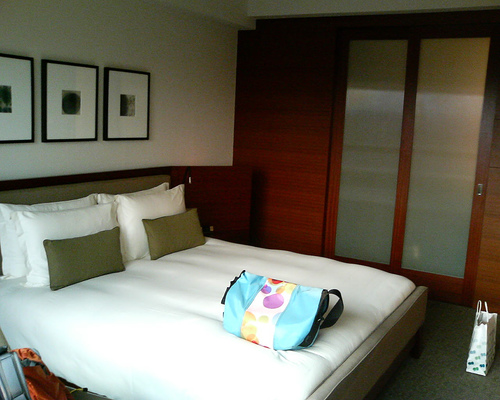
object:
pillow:
[42, 226, 124, 291]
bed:
[0, 172, 428, 400]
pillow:
[0, 193, 98, 278]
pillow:
[97, 181, 169, 205]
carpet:
[404, 307, 496, 399]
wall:
[1, 0, 238, 180]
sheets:
[0, 235, 417, 400]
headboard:
[0, 173, 170, 277]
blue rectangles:
[468, 361, 474, 365]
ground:
[399, 328, 470, 400]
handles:
[318, 289, 344, 324]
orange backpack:
[13, 346, 64, 398]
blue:
[294, 301, 311, 334]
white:
[253, 302, 262, 312]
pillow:
[142, 208, 205, 261]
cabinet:
[168, 166, 253, 247]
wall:
[249, 19, 344, 259]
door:
[322, 36, 499, 305]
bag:
[219, 270, 346, 352]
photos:
[40, 60, 100, 142]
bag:
[465, 299, 497, 375]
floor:
[387, 294, 500, 400]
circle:
[263, 293, 284, 308]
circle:
[261, 285, 272, 294]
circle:
[272, 279, 283, 284]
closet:
[234, 11, 500, 315]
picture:
[103, 66, 151, 142]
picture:
[0, 53, 35, 143]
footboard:
[307, 284, 428, 399]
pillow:
[15, 201, 118, 288]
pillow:
[116, 183, 187, 262]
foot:
[412, 332, 424, 359]